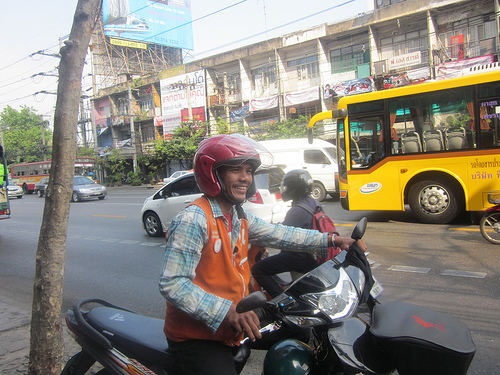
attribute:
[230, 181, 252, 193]
smile — broad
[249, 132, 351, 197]
van — white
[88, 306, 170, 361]
seat — black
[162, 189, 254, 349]
vest — orange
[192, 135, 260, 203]
helmet — red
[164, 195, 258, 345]
vest — orange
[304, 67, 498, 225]
bus — yellow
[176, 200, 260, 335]
vest — orange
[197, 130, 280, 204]
helmet — red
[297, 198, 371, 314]
backpack — red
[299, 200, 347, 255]
backpack — red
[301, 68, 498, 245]
bus — red, orange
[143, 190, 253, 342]
shirt — long sleeve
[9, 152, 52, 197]
bus — red